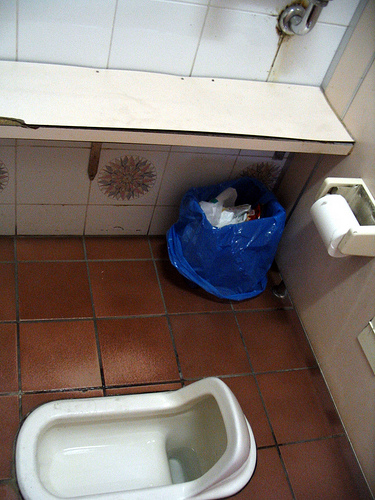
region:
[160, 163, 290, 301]
blue trashbag in trashcan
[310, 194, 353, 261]
roll of toilet paper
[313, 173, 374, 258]
toilet paper holder attached to wall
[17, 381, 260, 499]
urinal built in to floor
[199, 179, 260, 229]
trash in trash can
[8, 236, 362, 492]
brown tiles of bathroom floor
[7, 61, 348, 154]
shelf attached to wall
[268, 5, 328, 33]
silver pipe attached to wall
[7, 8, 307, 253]
white tiles on wall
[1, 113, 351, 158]
damaged edge of shelf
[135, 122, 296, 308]
a garbage can under a counter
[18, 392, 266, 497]
a white toilet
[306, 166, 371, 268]
a roll of toilet paper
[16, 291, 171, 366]
red tile floor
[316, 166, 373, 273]
a roll of toilet paper on a holder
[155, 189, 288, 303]
a blue garbage bag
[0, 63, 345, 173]
a white counter top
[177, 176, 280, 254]
garbage in a garbage can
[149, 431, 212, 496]
water in a toilet bowl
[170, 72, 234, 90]
nails in a counter top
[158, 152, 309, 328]
Trash can on the floor.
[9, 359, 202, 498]
Toilet on the floor.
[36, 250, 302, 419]
Tiles on the floor.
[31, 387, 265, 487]
Water in the toilet.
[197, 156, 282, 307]
Blue bag in the trash.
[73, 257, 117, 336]
Grout between the tiles.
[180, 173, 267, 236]
Trash in the can.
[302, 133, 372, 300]
Toilet paper on the wall.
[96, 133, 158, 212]
Design on the tile.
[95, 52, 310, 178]
shelf on the wall.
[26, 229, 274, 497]
A urinal in the floor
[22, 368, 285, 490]
A public bathroom with urinal in the floor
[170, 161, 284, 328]
The trash needs taken out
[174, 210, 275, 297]
The plastic liner is blue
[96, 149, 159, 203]
A decorative painted tile on the wall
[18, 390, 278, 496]
The urinal appears cleaner than the floor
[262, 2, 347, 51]
Rust and corrosion around a metal pipe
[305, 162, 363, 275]
Toilet paper haolder is on the wall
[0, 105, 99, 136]
The top of this shelf is broken and coming apart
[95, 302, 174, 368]
The tile on the floor is brown in color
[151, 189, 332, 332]
a blue trash bag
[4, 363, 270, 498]
a urinal in the floor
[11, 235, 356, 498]
red tile on the floor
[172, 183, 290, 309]
trash can full of trash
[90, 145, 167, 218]
a round circle design on wall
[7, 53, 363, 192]
a white bench on the wall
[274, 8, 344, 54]
silver plumbing above bench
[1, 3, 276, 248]
white tile on the wall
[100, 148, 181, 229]
colorful design on wall